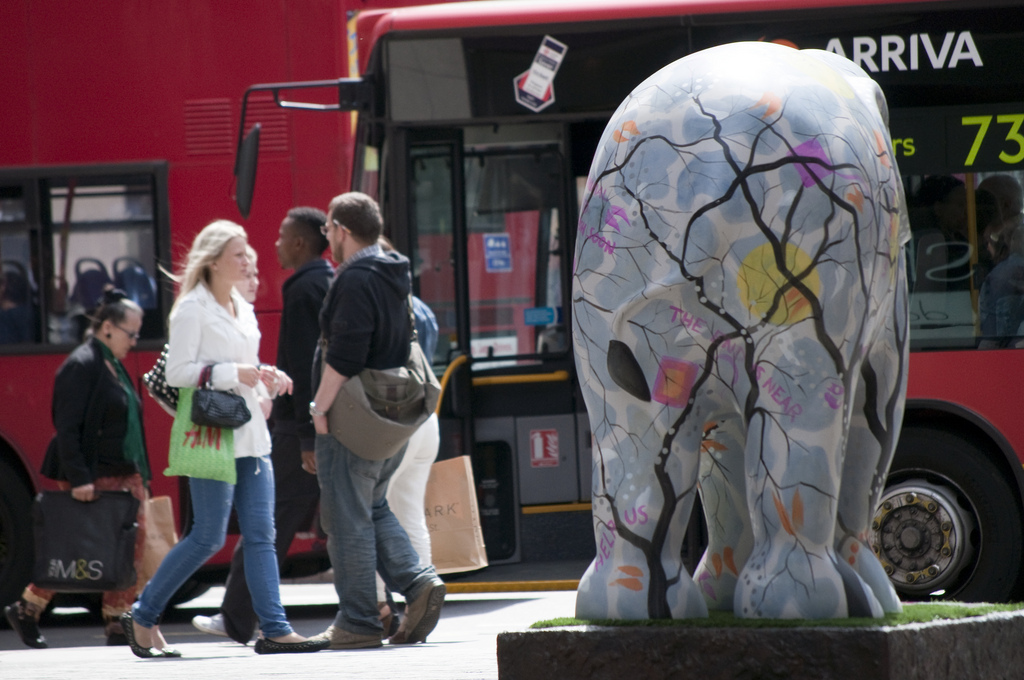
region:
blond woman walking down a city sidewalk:
[111, 215, 330, 661]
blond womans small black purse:
[191, 361, 252, 429]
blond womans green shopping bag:
[163, 364, 240, 486]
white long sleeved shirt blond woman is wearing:
[165, 275, 279, 460]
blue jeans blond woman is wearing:
[121, 449, 296, 643]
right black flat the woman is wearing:
[117, 607, 184, 664]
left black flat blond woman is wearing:
[248, 629, 334, 653]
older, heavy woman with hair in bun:
[1, 275, 157, 645]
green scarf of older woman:
[89, 324, 159, 484]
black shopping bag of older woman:
[24, 484, 141, 592]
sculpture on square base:
[495, 42, 1017, 676]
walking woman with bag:
[7, 284, 147, 645]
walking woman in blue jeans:
[123, 215, 323, 656]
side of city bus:
[234, 0, 1022, 602]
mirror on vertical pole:
[233, 78, 348, 216]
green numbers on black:
[963, 111, 1022, 166]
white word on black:
[824, 30, 981, 76]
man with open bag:
[306, 193, 442, 653]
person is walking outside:
[130, 217, 323, 654]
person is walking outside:
[308, 188, 446, 648]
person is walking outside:
[383, 289, 444, 581]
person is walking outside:
[265, 205, 360, 624]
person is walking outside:
[16, 293, 159, 644]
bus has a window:
[411, 157, 469, 369]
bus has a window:
[905, 176, 975, 347]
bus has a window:
[975, 173, 1021, 347]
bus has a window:
[354, 135, 386, 205]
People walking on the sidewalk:
[3, 190, 493, 665]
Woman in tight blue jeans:
[116, 211, 332, 664]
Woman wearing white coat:
[116, 215, 332, 662]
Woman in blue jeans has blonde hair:
[119, 212, 335, 661]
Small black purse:
[186, 360, 256, 433]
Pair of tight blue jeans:
[126, 458, 303, 639]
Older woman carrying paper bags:
[0, 278, 190, 651]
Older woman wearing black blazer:
[0, 281, 178, 655]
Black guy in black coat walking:
[189, 202, 351, 643]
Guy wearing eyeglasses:
[291, 190, 450, 652]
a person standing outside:
[306, 226, 456, 549]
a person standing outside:
[6, 321, 150, 540]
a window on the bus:
[382, 179, 466, 367]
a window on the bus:
[56, 186, 143, 351]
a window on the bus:
[0, 179, 30, 344]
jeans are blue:
[130, 459, 305, 606]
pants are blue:
[280, 418, 443, 597]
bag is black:
[19, 496, 140, 585]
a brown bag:
[287, 353, 465, 467]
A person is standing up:
[297, 201, 456, 635]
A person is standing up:
[123, 225, 332, 653]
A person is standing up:
[246, 194, 379, 647]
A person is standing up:
[187, 231, 267, 331]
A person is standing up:
[37, 270, 209, 637]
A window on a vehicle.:
[437, 117, 570, 392]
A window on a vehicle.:
[897, 168, 978, 349]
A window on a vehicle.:
[973, 156, 1021, 281]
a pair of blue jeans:
[151, 439, 287, 632]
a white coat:
[148, 293, 300, 453]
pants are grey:
[313, 397, 424, 600]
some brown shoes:
[319, 554, 444, 644]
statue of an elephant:
[495, 60, 1015, 608]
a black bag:
[29, 486, 140, 592]